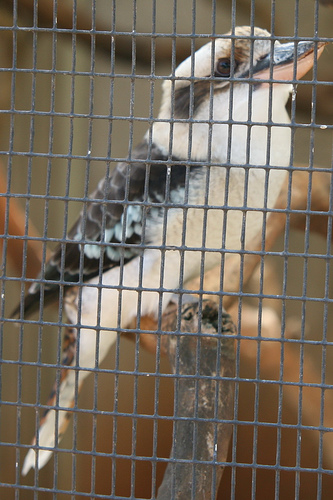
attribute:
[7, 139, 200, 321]
feathers — gray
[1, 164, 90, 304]
branch — blurred, brown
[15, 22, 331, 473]
bird — black, small, brown, white, gray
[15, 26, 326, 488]
feathers — white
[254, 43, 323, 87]
beak — two toned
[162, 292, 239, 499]
branch — tree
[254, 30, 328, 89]
beak — black, white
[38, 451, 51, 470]
tail — white, brown, black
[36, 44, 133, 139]
cage — black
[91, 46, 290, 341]
feathers — white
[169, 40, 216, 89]
crown — brown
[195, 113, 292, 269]
belly — white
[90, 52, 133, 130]
wire — metal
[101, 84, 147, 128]
wire — metal